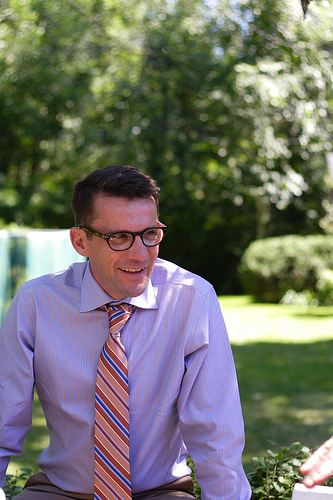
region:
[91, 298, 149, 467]
Knotted striped tie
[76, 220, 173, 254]
Glasses with black frame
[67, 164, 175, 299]
Man with short dark hair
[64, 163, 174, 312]
Man with glasses smiling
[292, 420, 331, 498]
Two fingers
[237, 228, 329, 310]
Bushes in the distance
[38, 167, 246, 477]
Man wearing dress shirt and tie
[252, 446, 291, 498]
Small green plant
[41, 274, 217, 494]
Dress shirt with tie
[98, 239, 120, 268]
Wrinkles on a man's face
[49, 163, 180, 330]
man with smiling face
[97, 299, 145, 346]
knot of striped tie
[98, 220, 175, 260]
glasses on man's face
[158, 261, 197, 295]
sun reflection on shoulder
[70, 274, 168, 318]
collar on dress shirt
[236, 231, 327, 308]
blurred bush in background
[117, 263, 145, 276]
teeth in man's mouth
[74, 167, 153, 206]
hair parted to one side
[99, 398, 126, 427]
blue stripe on tie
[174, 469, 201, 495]
pocket on tan pants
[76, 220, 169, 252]
Glasses on the man's face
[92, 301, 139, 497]
The man's tie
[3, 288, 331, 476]
Grass lawn behind the man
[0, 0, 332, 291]
The trees beyond the lawn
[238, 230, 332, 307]
The trimmed bushes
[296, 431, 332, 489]
the disembodied hand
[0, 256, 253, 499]
the shirt of the man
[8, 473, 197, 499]
The pants of the man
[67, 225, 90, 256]
The man's right ear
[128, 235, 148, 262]
The man's nose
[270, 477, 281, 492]
a green tree leaf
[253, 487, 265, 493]
a green tree leaf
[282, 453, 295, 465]
a green tree leaf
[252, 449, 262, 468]
a green tree leaf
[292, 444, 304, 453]
a green tree leaf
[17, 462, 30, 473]
a green tree leaf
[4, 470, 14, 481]
a green tree leaf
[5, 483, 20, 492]
a green tree leaf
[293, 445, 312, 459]
a green tree leaf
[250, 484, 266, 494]
a green tree leaf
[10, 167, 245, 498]
middle aged man sitting down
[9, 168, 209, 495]
man wearing glasses and a suit and tie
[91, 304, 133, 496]
orange, blue and white striped tie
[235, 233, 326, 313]
blurry green bushes in the background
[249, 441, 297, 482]
green leaves from a bush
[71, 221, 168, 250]
black eyeglasses on a man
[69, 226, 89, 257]
large white ear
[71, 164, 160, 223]
dark brown clean cut hair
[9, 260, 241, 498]
blue and orange striped button up shirt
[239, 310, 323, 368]
sun shining on grass